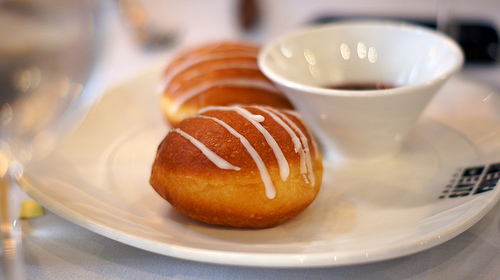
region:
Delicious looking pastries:
[149, 36, 314, 215]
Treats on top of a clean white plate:
[33, 34, 492, 270]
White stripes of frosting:
[185, 101, 331, 205]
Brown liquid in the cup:
[315, 65, 411, 100]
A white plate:
[35, 67, 498, 260]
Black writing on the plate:
[439, 141, 499, 210]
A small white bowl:
[260, 8, 461, 165]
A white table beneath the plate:
[27, 217, 92, 278]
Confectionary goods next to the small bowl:
[155, 13, 311, 223]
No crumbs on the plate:
[322, 156, 374, 238]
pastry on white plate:
[168, 100, 305, 204]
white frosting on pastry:
[192, 143, 249, 175]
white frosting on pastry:
[256, 169, 276, 198]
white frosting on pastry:
[268, 143, 292, 184]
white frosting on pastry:
[299, 158, 314, 188]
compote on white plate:
[308, 35, 435, 166]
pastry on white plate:
[141, 47, 247, 99]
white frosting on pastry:
[203, 79, 249, 98]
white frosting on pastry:
[216, 61, 246, 71]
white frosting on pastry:
[206, 52, 237, 62]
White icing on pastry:
[174, 121, 243, 181]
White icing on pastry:
[189, 107, 281, 203]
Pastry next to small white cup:
[153, 104, 323, 231]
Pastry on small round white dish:
[148, 101, 327, 225]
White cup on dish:
[259, 20, 466, 153]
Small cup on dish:
[257, 21, 463, 166]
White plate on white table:
[14, 69, 499, 263]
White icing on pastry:
[162, 74, 287, 116]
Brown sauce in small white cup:
[313, 70, 410, 92]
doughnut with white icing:
[130, 100, 311, 215]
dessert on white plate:
[115, 57, 417, 244]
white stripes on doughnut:
[190, 120, 290, 179]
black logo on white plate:
[438, 148, 498, 216]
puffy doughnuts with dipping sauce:
[127, 43, 372, 265]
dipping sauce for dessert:
[245, 20, 450, 171]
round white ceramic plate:
[318, 159, 465, 226]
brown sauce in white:
[330, 64, 392, 121]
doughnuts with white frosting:
[110, 40, 498, 277]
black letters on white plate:
[434, 135, 476, 212]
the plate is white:
[307, 187, 351, 259]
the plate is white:
[354, 228, 384, 276]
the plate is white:
[337, 209, 382, 276]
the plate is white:
[359, 165, 412, 245]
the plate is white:
[351, 191, 387, 228]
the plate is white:
[345, 256, 352, 271]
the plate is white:
[351, 210, 396, 278]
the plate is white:
[326, 236, 376, 272]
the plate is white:
[349, 203, 405, 273]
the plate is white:
[365, 219, 435, 264]